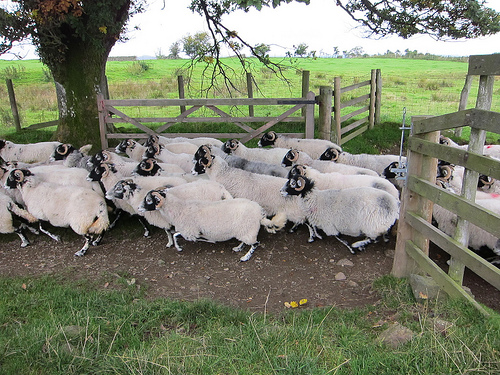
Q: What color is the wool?
A: White.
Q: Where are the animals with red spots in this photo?
A: Right side.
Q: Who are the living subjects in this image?
A: The sheep.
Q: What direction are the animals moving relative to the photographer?
A: Left.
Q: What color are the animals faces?
A: Black and white.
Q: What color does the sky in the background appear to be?
A: White.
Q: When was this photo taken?
A: During the day.